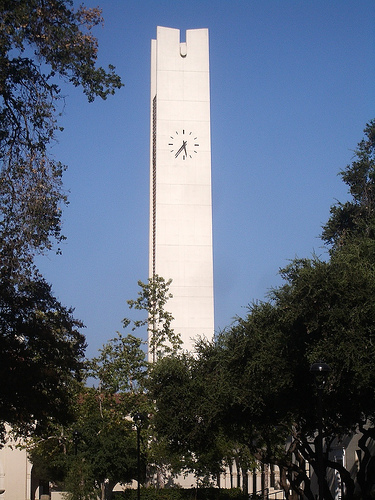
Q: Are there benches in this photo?
A: No, there are no benches.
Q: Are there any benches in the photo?
A: No, there are no benches.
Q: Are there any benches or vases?
A: No, there are no benches or vases.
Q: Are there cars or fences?
A: No, there are no fences or cars.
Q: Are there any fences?
A: No, there are no fences.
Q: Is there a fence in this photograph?
A: No, there are no fences.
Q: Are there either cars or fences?
A: No, there are no fences or cars.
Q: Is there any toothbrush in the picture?
A: No, there are no toothbrushes.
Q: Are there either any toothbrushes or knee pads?
A: No, there are no toothbrushes or knee pads.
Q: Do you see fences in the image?
A: No, there are no fences.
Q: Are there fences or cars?
A: No, there are no fences or cars.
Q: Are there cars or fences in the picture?
A: No, there are no fences or cars.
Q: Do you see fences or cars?
A: No, there are no fences or cars.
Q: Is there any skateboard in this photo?
A: No, there are no skateboards.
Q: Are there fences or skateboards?
A: No, there are no skateboards or fences.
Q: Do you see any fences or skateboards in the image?
A: No, there are no skateboards or fences.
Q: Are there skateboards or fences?
A: No, there are no skateboards or fences.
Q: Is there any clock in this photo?
A: Yes, there is a clock.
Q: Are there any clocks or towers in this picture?
A: Yes, there is a clock.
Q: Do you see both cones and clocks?
A: No, there is a clock but no cones.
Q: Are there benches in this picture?
A: No, there are no benches.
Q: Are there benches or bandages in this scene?
A: No, there are no benches or bandages.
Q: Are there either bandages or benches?
A: No, there are no benches or bandages.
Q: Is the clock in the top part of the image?
A: Yes, the clock is in the top of the image.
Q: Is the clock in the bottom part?
A: No, the clock is in the top of the image.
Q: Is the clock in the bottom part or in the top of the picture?
A: The clock is in the top of the image.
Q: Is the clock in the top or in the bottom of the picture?
A: The clock is in the top of the image.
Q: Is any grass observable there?
A: Yes, there is grass.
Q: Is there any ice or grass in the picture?
A: Yes, there is grass.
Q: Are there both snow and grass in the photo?
A: No, there is grass but no snow.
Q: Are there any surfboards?
A: No, there are no surfboards.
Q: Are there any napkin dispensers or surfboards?
A: No, there are no surfboards or napkin dispensers.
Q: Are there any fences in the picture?
A: No, there are no fences.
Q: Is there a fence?
A: No, there are no fences.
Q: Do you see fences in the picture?
A: No, there are no fences.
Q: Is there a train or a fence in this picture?
A: No, there are no fences or trains.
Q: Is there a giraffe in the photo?
A: No, there are no giraffes.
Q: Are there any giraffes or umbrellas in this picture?
A: No, there are no giraffes or umbrellas.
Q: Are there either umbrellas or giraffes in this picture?
A: No, there are no giraffes or umbrellas.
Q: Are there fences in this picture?
A: No, there are no fences.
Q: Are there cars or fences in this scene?
A: No, there are no fences or cars.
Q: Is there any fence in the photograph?
A: No, there are no fences.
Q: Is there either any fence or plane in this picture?
A: No, there are no fences or airplanes.